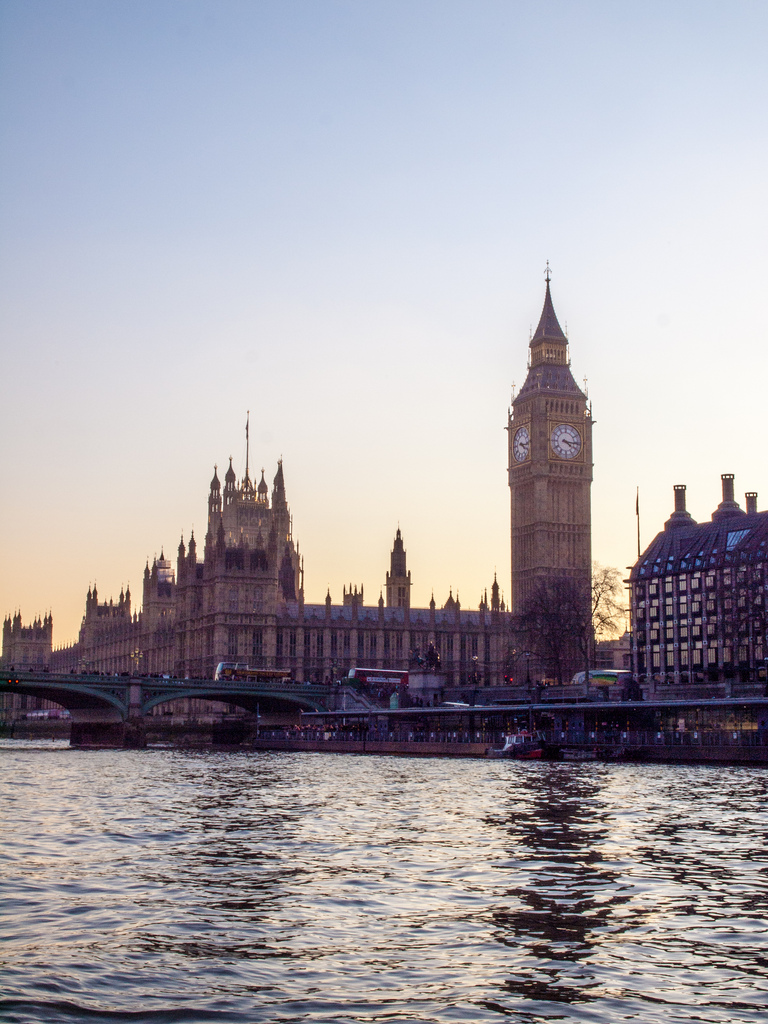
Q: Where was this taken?
A: River.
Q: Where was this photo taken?
A: London.